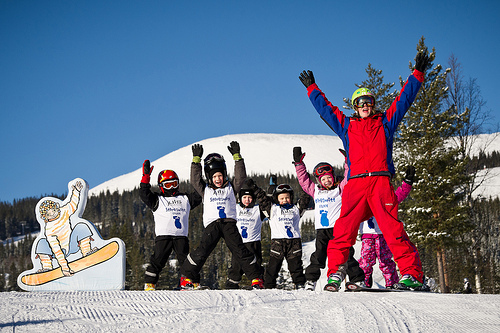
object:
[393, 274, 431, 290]
boots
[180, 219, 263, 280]
pants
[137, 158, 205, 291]
child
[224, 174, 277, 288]
child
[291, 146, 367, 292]
child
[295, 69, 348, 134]
arm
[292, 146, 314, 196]
arm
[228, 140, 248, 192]
arm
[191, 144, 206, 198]
arm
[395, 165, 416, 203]
arm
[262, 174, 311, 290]
child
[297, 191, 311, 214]
arm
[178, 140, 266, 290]
child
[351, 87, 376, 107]
helmet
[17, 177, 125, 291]
snowboarder sign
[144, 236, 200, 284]
pants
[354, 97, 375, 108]
goggles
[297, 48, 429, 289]
adult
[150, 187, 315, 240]
children shirts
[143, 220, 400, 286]
childs pants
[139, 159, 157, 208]
arm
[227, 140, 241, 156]
glove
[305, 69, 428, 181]
coat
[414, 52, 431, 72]
hands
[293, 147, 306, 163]
hands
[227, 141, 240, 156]
hands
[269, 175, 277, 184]
hands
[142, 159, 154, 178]
hands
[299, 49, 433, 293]
they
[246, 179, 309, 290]
they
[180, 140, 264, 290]
they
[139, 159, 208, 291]
they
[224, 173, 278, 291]
they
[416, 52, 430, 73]
gloves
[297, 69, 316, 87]
gloves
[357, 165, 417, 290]
child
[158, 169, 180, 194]
helmet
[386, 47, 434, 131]
arm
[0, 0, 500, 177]
sky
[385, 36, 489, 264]
tree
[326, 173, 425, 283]
pants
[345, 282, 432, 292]
snowboarder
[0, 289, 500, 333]
slope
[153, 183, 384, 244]
participation vest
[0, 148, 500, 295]
trees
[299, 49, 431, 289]
teacher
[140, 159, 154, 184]
glove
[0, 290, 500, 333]
tracks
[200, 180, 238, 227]
shirt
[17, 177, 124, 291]
picture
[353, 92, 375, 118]
head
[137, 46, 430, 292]
class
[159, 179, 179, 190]
snow glasses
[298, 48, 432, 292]
child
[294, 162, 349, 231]
coat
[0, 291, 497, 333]
snow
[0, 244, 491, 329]
mountainside